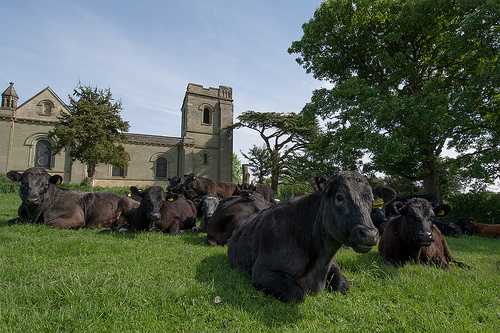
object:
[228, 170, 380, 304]
black cow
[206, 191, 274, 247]
cow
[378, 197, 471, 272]
cow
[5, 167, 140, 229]
cow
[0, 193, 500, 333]
field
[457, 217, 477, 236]
cow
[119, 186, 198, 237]
cow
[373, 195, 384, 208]
tag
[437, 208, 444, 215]
tag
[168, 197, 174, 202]
tag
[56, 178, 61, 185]
tag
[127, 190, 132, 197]
tag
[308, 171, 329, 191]
ear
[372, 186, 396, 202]
ear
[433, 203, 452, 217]
ear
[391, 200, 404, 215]
ear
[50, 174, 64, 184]
ear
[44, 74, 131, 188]
small tree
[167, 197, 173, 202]
tag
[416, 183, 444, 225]
ground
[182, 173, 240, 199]
cow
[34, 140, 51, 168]
door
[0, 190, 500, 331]
grass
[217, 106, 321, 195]
small tree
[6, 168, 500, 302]
cattles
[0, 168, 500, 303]
cows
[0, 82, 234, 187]
building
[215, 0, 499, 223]
tree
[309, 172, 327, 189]
black ears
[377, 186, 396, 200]
black ears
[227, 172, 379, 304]
in front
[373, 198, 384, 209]
yellow tag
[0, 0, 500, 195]
sky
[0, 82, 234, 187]
windows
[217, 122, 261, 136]
stem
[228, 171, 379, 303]
cow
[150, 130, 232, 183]
shadow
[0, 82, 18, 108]
temple